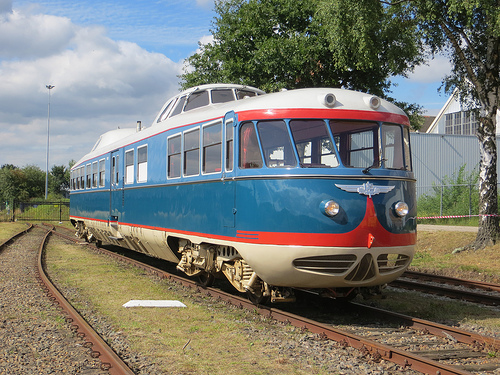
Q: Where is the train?
A: On the tracks.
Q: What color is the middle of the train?
A: Blue.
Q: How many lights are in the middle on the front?
A: 2.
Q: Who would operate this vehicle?
A: Engineer.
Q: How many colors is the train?
A: 3.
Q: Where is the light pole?
A: Behind the train.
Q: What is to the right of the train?
A: Tree.